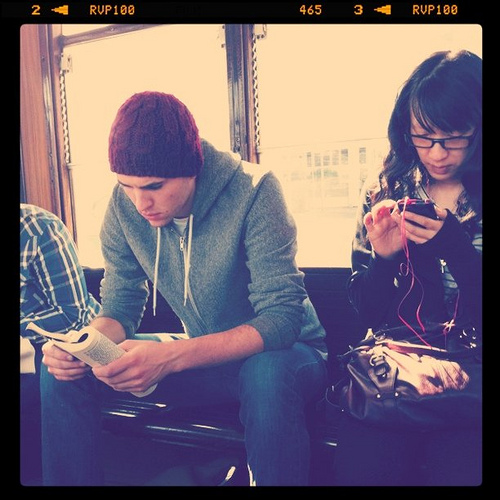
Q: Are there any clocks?
A: No, there are no clocks.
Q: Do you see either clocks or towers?
A: No, there are no clocks or towers.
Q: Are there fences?
A: No, there are no fences.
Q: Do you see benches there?
A: Yes, there is a bench.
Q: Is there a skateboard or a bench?
A: Yes, there is a bench.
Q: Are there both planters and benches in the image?
A: No, there is a bench but no planters.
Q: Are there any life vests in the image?
A: No, there are no life vests.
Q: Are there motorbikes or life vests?
A: No, there are no life vests or motorbikes.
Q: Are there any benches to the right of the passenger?
A: Yes, there is a bench to the right of the passenger.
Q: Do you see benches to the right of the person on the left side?
A: Yes, there is a bench to the right of the passenger.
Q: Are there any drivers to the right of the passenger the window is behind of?
A: No, there is a bench to the right of the passenger.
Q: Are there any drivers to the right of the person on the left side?
A: No, there is a bench to the right of the passenger.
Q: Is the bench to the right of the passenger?
A: Yes, the bench is to the right of the passenger.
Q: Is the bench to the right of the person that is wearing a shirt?
A: Yes, the bench is to the right of the passenger.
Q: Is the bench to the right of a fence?
A: No, the bench is to the right of the passenger.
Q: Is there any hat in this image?
A: Yes, there is a hat.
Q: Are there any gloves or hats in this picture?
A: Yes, there is a hat.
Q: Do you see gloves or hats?
A: Yes, there is a hat.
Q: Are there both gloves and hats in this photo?
A: No, there is a hat but no gloves.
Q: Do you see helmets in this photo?
A: No, there are no helmets.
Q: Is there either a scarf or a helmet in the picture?
A: No, there are no helmets or scarves.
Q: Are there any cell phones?
A: Yes, there is a cell phone.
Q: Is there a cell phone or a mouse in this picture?
A: Yes, there is a cell phone.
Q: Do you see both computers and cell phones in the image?
A: No, there is a cell phone but no computers.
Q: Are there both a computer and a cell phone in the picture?
A: No, there is a cell phone but no computers.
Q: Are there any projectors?
A: No, there are no projectors.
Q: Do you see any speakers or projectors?
A: No, there are no projectors or speakers.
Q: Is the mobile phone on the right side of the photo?
A: Yes, the mobile phone is on the right of the image.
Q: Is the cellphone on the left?
A: No, the cellphone is on the right of the image.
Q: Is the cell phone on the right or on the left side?
A: The cell phone is on the right of the image.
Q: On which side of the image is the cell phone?
A: The cell phone is on the right of the image.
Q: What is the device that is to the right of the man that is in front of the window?
A: The device is a cell phone.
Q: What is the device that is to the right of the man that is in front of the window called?
A: The device is a cell phone.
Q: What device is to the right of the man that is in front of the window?
A: The device is a cell phone.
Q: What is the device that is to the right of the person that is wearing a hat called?
A: The device is a cell phone.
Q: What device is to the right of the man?
A: The device is a cell phone.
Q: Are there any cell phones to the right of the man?
A: Yes, there is a cell phone to the right of the man.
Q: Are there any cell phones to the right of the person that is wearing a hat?
A: Yes, there is a cell phone to the right of the man.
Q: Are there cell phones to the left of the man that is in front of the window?
A: No, the cell phone is to the right of the man.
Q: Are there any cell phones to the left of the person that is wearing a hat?
A: No, the cell phone is to the right of the man.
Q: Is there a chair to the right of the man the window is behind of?
A: No, there is a cell phone to the right of the man.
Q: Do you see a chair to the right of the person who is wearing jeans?
A: No, there is a cell phone to the right of the man.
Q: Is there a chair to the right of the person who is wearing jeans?
A: No, there is a cell phone to the right of the man.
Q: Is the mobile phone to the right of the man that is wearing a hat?
A: Yes, the mobile phone is to the right of the man.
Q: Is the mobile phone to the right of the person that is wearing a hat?
A: Yes, the mobile phone is to the right of the man.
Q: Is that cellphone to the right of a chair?
A: No, the cellphone is to the right of the man.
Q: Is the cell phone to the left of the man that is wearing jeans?
A: No, the cell phone is to the right of the man.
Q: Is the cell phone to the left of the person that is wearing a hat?
A: No, the cell phone is to the right of the man.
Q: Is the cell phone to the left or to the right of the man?
A: The cell phone is to the right of the man.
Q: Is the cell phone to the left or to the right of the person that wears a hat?
A: The cell phone is to the right of the man.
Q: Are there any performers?
A: No, there are no performers.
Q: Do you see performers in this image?
A: No, there are no performers.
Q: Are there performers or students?
A: No, there are no performers or students.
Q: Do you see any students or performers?
A: No, there are no performers or students.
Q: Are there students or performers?
A: No, there are no performers or students.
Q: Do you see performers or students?
A: No, there are no performers or students.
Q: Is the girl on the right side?
A: Yes, the girl is on the right of the image.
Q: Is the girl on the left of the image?
A: No, the girl is on the right of the image.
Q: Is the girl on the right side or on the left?
A: The girl is on the right of the image.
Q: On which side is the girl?
A: The girl is on the right of the image.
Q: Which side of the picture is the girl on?
A: The girl is on the right of the image.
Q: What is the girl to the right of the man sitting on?
A: The girl is sitting on the bench.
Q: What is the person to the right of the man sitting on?
A: The girl is sitting on the bench.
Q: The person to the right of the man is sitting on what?
A: The girl is sitting on the bench.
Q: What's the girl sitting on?
A: The girl is sitting on the bench.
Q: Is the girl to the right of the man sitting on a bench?
A: Yes, the girl is sitting on a bench.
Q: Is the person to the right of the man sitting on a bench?
A: Yes, the girl is sitting on a bench.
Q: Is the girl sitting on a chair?
A: No, the girl is sitting on a bench.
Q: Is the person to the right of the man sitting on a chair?
A: No, the girl is sitting on a bench.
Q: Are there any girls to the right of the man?
A: Yes, there is a girl to the right of the man.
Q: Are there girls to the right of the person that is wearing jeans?
A: Yes, there is a girl to the right of the man.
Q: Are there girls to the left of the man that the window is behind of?
A: No, the girl is to the right of the man.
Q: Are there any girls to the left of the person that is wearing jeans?
A: No, the girl is to the right of the man.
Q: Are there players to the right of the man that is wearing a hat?
A: No, there is a girl to the right of the man.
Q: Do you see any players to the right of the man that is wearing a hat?
A: No, there is a girl to the right of the man.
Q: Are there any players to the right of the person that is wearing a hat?
A: No, there is a girl to the right of the man.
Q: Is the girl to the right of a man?
A: Yes, the girl is to the right of a man.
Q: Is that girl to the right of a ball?
A: No, the girl is to the right of a man.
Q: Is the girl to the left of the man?
A: No, the girl is to the right of the man.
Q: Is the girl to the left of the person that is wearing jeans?
A: No, the girl is to the right of the man.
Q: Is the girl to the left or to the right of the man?
A: The girl is to the right of the man.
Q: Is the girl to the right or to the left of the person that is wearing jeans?
A: The girl is to the right of the man.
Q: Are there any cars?
A: No, there are no cars.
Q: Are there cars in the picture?
A: No, there are no cars.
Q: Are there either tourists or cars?
A: No, there are no cars or tourists.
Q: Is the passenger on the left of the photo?
A: Yes, the passenger is on the left of the image.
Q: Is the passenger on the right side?
A: No, the passenger is on the left of the image.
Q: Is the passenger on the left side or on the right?
A: The passenger is on the left of the image.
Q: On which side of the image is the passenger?
A: The passenger is on the left of the image.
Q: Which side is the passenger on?
A: The passenger is on the left of the image.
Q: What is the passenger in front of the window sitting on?
A: The passenger is sitting on the bench.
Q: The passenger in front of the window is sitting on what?
A: The passenger is sitting on the bench.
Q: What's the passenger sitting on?
A: The passenger is sitting on the bench.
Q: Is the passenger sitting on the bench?
A: Yes, the passenger is sitting on the bench.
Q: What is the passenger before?
A: The passenger is in front of the window.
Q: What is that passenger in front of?
A: The passenger is in front of the window.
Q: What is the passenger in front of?
A: The passenger is in front of the window.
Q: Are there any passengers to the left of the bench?
A: Yes, there is a passenger to the left of the bench.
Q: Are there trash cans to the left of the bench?
A: No, there is a passenger to the left of the bench.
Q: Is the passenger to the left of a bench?
A: Yes, the passenger is to the left of a bench.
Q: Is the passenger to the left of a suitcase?
A: No, the passenger is to the left of a bench.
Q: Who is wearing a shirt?
A: The passenger is wearing a shirt.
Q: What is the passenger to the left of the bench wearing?
A: The passenger is wearing a shirt.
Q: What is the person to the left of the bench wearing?
A: The passenger is wearing a shirt.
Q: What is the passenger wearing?
A: The passenger is wearing a shirt.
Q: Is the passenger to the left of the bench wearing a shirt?
A: Yes, the passenger is wearing a shirt.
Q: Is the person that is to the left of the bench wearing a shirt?
A: Yes, the passenger is wearing a shirt.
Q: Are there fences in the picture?
A: No, there are no fences.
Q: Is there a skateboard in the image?
A: No, there are no skateboards.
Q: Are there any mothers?
A: No, there are no mothers.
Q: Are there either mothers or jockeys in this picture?
A: No, there are no mothers or jockeys.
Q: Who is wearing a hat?
A: The man is wearing a hat.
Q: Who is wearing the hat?
A: The man is wearing a hat.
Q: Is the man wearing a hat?
A: Yes, the man is wearing a hat.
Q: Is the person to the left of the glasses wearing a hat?
A: Yes, the man is wearing a hat.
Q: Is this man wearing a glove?
A: No, the man is wearing a hat.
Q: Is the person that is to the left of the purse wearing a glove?
A: No, the man is wearing a hat.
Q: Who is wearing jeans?
A: The man is wearing jeans.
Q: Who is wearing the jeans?
A: The man is wearing jeans.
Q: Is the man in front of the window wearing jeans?
A: Yes, the man is wearing jeans.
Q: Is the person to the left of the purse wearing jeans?
A: Yes, the man is wearing jeans.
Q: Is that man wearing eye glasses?
A: No, the man is wearing jeans.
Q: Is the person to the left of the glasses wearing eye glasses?
A: No, the man is wearing jeans.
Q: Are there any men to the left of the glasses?
A: Yes, there is a man to the left of the glasses.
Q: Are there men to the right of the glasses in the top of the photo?
A: No, the man is to the left of the glasses.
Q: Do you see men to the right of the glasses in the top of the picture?
A: No, the man is to the left of the glasses.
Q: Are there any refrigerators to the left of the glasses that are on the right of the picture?
A: No, there is a man to the left of the glasses.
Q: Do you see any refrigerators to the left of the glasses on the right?
A: No, there is a man to the left of the glasses.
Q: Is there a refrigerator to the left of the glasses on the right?
A: No, there is a man to the left of the glasses.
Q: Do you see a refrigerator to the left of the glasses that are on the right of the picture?
A: No, there is a man to the left of the glasses.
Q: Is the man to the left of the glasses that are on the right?
A: Yes, the man is to the left of the glasses.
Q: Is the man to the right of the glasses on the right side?
A: No, the man is to the left of the glasses.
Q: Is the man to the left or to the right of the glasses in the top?
A: The man is to the left of the glasses.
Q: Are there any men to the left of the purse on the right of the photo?
A: Yes, there is a man to the left of the purse.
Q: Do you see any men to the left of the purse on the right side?
A: Yes, there is a man to the left of the purse.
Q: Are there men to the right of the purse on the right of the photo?
A: No, the man is to the left of the purse.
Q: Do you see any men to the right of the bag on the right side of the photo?
A: No, the man is to the left of the purse.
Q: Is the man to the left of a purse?
A: Yes, the man is to the left of a purse.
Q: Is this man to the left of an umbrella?
A: No, the man is to the left of a purse.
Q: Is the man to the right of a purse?
A: No, the man is to the left of a purse.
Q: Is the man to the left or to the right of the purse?
A: The man is to the left of the purse.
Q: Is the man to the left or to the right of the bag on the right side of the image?
A: The man is to the left of the purse.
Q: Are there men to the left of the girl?
A: Yes, there is a man to the left of the girl.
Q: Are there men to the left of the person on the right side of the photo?
A: Yes, there is a man to the left of the girl.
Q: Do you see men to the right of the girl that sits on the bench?
A: No, the man is to the left of the girl.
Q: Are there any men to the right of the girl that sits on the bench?
A: No, the man is to the left of the girl.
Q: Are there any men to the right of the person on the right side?
A: No, the man is to the left of the girl.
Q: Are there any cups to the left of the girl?
A: No, there is a man to the left of the girl.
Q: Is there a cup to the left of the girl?
A: No, there is a man to the left of the girl.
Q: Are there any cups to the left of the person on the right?
A: No, there is a man to the left of the girl.